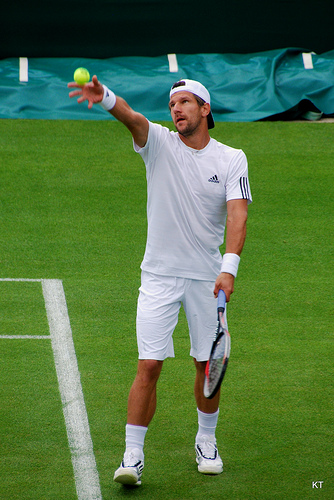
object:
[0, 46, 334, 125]
tarp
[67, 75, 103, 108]
hand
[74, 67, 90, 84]
ball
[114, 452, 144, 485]
shoes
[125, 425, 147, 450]
white socks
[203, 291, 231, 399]
tennis racket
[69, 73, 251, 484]
man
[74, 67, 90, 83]
tennis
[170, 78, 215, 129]
hat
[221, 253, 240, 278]
wrist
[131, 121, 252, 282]
shirt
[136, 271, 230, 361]
shorts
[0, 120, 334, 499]
grass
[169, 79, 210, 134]
head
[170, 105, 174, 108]
eye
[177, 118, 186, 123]
mouth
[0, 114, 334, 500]
tennis court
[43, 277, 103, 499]
white line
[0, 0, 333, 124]
background